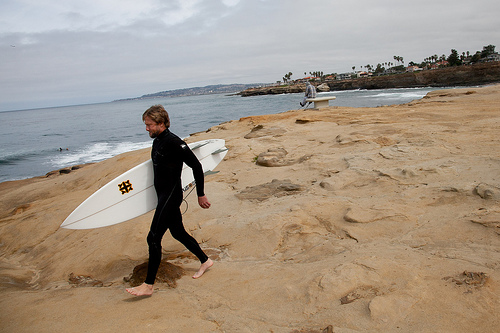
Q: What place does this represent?
A: It represents the beach.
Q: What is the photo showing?
A: It is showing a beach.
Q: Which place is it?
A: It is a beach.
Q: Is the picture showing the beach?
A: Yes, it is showing the beach.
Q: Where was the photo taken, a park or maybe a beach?
A: It was taken at a beach.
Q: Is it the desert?
A: No, it is the beach.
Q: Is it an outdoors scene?
A: Yes, it is outdoors.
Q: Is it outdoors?
A: Yes, it is outdoors.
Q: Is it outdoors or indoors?
A: It is outdoors.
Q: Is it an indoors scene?
A: No, it is outdoors.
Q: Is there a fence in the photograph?
A: No, there are no fences.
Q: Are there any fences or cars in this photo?
A: No, there are no fences or cars.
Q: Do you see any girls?
A: No, there are no girls.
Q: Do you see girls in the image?
A: No, there are no girls.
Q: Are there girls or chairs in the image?
A: No, there are no girls or chairs.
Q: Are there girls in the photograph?
A: No, there are no girls.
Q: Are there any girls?
A: No, there are no girls.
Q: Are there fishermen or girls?
A: No, there are no girls or fishermen.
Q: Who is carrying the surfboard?
A: The man is carrying the surfboard.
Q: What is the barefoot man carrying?
A: The man is carrying a surfboard.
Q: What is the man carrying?
A: The man is carrying a surfboard.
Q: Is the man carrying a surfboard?
A: Yes, the man is carrying a surfboard.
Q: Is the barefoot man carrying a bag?
A: No, the man is carrying a surfboard.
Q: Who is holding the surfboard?
A: The man is holding the surfboard.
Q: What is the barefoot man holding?
A: The man is holding the surfboard.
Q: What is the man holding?
A: The man is holding the surfboard.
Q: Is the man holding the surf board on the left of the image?
A: Yes, the man is holding the surfboard.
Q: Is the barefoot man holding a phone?
A: No, the man is holding the surfboard.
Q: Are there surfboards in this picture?
A: Yes, there is a surfboard.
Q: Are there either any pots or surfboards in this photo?
A: Yes, there is a surfboard.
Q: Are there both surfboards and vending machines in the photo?
A: No, there is a surfboard but no vending machines.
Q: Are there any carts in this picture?
A: No, there are no carts.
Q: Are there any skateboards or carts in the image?
A: No, there are no carts or skateboards.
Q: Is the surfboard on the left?
A: Yes, the surfboard is on the left of the image.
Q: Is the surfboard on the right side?
A: No, the surfboard is on the left of the image.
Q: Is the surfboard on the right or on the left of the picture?
A: The surfboard is on the left of the image.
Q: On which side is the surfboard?
A: The surfboard is on the left of the image.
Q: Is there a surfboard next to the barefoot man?
A: Yes, there is a surfboard next to the man.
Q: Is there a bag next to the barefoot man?
A: No, there is a surfboard next to the man.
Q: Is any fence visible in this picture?
A: No, there are no fences.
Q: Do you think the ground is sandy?
A: Yes, the ground is sandy.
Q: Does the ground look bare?
A: No, the ground is sandy.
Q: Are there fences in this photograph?
A: No, there are no fences.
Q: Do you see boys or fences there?
A: No, there are no fences or boys.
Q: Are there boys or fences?
A: No, there are no fences or boys.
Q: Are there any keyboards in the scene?
A: No, there are no keyboards.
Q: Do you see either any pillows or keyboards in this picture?
A: No, there are no keyboards or pillows.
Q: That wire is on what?
A: The wire is on the surfboard.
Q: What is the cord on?
A: The wire is on the surfboard.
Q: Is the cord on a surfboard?
A: Yes, the cord is on a surfboard.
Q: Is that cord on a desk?
A: No, the cord is on a surfboard.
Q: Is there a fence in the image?
A: No, there are no fences.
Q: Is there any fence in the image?
A: No, there are no fences.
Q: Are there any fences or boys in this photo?
A: No, there are no fences or boys.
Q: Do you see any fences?
A: No, there are no fences.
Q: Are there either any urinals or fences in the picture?
A: No, there are no fences or urinals.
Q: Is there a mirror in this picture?
A: No, there are no mirrors.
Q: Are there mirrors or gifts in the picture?
A: No, there are no mirrors or gifts.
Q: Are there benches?
A: Yes, there is a bench.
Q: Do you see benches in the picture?
A: Yes, there is a bench.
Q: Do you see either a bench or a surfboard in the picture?
A: Yes, there is a bench.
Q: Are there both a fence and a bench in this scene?
A: No, there is a bench but no fences.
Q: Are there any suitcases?
A: No, there are no suitcases.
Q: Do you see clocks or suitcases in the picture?
A: No, there are no suitcases or clocks.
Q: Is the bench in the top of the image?
A: Yes, the bench is in the top of the image.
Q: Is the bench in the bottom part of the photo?
A: No, the bench is in the top of the image.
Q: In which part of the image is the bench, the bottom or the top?
A: The bench is in the top of the image.